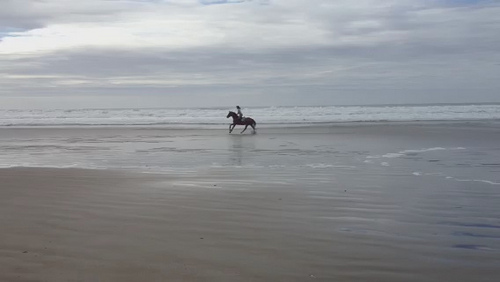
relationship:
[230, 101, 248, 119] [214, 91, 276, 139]
person on horse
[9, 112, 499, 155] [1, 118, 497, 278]
waves hitting sand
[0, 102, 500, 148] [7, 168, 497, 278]
waves hitting sand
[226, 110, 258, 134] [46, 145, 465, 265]
horse on beach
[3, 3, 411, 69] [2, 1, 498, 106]
cloud in sky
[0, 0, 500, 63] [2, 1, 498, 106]
cloud in sky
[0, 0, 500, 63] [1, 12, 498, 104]
cloud in sky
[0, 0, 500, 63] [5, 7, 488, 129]
cloud in sky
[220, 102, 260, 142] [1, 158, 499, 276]
horse on beach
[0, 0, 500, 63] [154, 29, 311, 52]
cloud in sky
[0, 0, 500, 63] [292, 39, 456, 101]
cloud in sky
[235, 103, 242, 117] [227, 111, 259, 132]
woman riding horse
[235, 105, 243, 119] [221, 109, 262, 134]
woman on horse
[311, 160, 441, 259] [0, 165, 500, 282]
ripples in hitting sand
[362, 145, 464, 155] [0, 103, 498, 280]
froth in water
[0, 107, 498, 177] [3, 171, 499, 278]
water onto shore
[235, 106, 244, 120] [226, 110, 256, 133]
person on horse